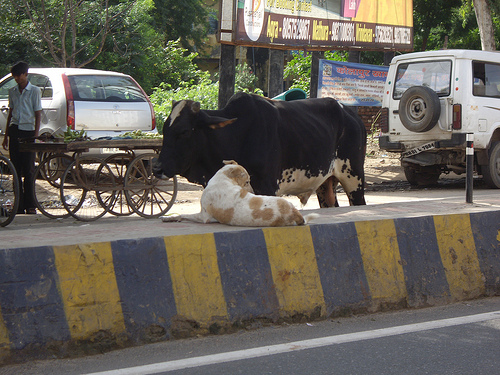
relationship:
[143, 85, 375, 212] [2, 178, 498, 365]
cow on a sidewalk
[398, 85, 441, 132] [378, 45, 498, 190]
tire on jeep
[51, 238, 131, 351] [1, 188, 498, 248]
stripe on sidewalk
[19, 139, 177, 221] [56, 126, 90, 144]
bike has vegetable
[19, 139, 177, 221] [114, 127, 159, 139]
bike has vegetable